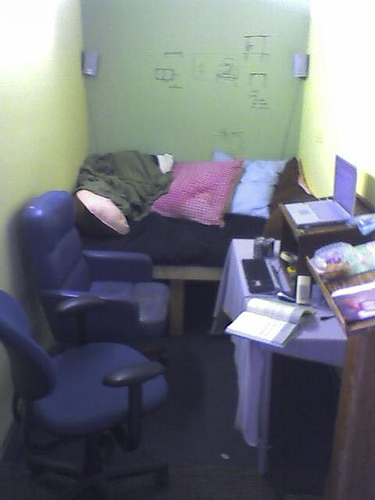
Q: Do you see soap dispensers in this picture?
A: No, there are no soap dispensers.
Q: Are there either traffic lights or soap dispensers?
A: No, there are no soap dispensers or traffic lights.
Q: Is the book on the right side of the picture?
A: Yes, the book is on the right of the image.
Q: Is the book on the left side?
A: No, the book is on the right of the image.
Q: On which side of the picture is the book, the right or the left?
A: The book is on the right of the image.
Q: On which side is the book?
A: The book is on the right of the image.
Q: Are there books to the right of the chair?
A: Yes, there is a book to the right of the chair.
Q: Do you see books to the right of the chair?
A: Yes, there is a book to the right of the chair.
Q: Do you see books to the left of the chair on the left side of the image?
A: No, the book is to the right of the chair.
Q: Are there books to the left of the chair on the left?
A: No, the book is to the right of the chair.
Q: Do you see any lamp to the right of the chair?
A: No, there is a book to the right of the chair.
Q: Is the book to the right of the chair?
A: Yes, the book is to the right of the chair.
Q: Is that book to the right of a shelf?
A: No, the book is to the right of the chair.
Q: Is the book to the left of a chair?
A: No, the book is to the right of a chair.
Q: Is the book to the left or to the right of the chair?
A: The book is to the right of the chair.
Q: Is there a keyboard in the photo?
A: Yes, there is a keyboard.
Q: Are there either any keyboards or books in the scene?
A: Yes, there is a keyboard.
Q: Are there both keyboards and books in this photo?
A: Yes, there are both a keyboard and a book.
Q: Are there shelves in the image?
A: No, there are no shelves.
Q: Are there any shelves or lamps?
A: No, there are no shelves or lamps.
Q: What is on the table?
A: The keyboard is on the table.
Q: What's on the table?
A: The keyboard is on the table.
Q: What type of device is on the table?
A: The device is a keyboard.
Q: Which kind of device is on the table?
A: The device is a keyboard.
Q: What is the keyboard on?
A: The keyboard is on the table.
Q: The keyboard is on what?
A: The keyboard is on the table.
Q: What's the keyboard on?
A: The keyboard is on the table.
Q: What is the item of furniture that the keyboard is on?
A: The piece of furniture is a table.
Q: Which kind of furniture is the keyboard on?
A: The keyboard is on the table.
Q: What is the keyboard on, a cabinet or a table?
A: The keyboard is on a table.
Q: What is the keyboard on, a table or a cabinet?
A: The keyboard is on a table.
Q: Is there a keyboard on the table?
A: Yes, there is a keyboard on the table.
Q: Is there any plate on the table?
A: No, there is a keyboard on the table.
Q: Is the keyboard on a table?
A: Yes, the keyboard is on a table.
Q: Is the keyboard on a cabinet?
A: No, the keyboard is on a table.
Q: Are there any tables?
A: Yes, there is a table.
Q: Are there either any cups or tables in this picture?
A: Yes, there is a table.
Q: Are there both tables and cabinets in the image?
A: No, there is a table but no cabinets.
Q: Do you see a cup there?
A: No, there are no cups.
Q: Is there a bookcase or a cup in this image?
A: No, there are no cups or bookcases.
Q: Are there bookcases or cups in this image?
A: No, there are no cups or bookcases.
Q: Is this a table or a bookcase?
A: This is a table.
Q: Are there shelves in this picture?
A: No, there are no shelves.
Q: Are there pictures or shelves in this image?
A: No, there are no shelves or pictures.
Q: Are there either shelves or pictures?
A: No, there are no shelves or pictures.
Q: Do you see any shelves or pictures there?
A: No, there are no shelves or pictures.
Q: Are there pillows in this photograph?
A: Yes, there is a pillow.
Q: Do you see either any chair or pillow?
A: Yes, there is a pillow.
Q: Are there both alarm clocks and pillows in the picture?
A: No, there is a pillow but no alarm clocks.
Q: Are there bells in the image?
A: No, there are no bells.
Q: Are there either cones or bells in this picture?
A: No, there are no bells or cones.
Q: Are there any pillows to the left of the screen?
A: Yes, there is a pillow to the left of the screen.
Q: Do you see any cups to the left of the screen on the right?
A: No, there is a pillow to the left of the screen.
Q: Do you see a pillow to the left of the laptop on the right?
A: Yes, there is a pillow to the left of the laptop.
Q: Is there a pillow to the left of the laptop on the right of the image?
A: Yes, there is a pillow to the left of the laptop.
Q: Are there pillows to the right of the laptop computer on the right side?
A: No, the pillow is to the left of the laptop.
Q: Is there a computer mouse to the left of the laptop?
A: No, there is a pillow to the left of the laptop.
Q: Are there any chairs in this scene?
A: Yes, there is a chair.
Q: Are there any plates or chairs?
A: Yes, there is a chair.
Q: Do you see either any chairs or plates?
A: Yes, there is a chair.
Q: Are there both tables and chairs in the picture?
A: Yes, there are both a chair and a table.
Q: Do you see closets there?
A: No, there are no closets.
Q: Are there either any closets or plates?
A: No, there are no closets or plates.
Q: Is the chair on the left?
A: Yes, the chair is on the left of the image.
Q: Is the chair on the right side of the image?
A: No, the chair is on the left of the image.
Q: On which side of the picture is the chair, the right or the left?
A: The chair is on the left of the image.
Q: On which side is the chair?
A: The chair is on the left of the image.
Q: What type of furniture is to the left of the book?
A: The piece of furniture is a chair.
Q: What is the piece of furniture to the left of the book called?
A: The piece of furniture is a chair.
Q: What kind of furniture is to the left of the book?
A: The piece of furniture is a chair.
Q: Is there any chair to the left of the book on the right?
A: Yes, there is a chair to the left of the book.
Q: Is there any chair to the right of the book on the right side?
A: No, the chair is to the left of the book.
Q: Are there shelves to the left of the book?
A: No, there is a chair to the left of the book.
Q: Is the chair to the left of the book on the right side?
A: Yes, the chair is to the left of the book.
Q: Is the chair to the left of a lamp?
A: No, the chair is to the left of the book.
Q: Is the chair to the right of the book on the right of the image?
A: No, the chair is to the left of the book.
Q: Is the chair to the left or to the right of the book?
A: The chair is to the left of the book.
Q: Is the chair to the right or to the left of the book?
A: The chair is to the left of the book.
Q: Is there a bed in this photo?
A: Yes, there is a bed.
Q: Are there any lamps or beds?
A: Yes, there is a bed.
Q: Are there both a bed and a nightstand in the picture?
A: No, there is a bed but no nightstands.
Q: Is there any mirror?
A: No, there are no mirrors.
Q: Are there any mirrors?
A: No, there are no mirrors.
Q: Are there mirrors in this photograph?
A: No, there are no mirrors.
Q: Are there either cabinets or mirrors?
A: No, there are no mirrors or cabinets.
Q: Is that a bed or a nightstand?
A: That is a bed.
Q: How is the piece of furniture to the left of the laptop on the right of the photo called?
A: The piece of furniture is a bed.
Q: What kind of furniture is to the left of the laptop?
A: The piece of furniture is a bed.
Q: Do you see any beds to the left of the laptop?
A: Yes, there is a bed to the left of the laptop.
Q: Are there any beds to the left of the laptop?
A: Yes, there is a bed to the left of the laptop.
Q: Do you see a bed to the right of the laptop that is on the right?
A: No, the bed is to the left of the laptop.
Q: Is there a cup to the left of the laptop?
A: No, there is a bed to the left of the laptop.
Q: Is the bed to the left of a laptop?
A: Yes, the bed is to the left of a laptop.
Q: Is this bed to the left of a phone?
A: No, the bed is to the left of a laptop.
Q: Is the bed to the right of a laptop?
A: No, the bed is to the left of a laptop.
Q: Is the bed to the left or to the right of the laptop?
A: The bed is to the left of the laptop.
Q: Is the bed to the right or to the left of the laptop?
A: The bed is to the left of the laptop.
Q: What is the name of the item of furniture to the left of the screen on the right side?
A: The piece of furniture is a bed.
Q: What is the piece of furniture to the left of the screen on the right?
A: The piece of furniture is a bed.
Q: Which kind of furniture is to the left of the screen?
A: The piece of furniture is a bed.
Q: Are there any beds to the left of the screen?
A: Yes, there is a bed to the left of the screen.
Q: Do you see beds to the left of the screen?
A: Yes, there is a bed to the left of the screen.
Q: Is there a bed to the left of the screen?
A: Yes, there is a bed to the left of the screen.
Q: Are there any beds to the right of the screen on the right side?
A: No, the bed is to the left of the screen.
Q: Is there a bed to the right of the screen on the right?
A: No, the bed is to the left of the screen.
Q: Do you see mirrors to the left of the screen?
A: No, there is a bed to the left of the screen.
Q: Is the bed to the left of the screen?
A: Yes, the bed is to the left of the screen.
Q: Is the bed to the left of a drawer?
A: No, the bed is to the left of the screen.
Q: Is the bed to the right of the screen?
A: No, the bed is to the left of the screen.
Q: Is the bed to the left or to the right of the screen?
A: The bed is to the left of the screen.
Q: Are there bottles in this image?
A: No, there are no bottles.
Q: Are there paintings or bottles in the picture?
A: No, there are no bottles or paintings.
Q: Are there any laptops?
A: Yes, there is a laptop.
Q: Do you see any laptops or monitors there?
A: Yes, there is a laptop.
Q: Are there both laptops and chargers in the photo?
A: No, there is a laptop but no chargers.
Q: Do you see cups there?
A: No, there are no cups.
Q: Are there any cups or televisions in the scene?
A: No, there are no cups or televisions.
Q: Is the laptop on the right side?
A: Yes, the laptop is on the right of the image.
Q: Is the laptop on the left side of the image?
A: No, the laptop is on the right of the image.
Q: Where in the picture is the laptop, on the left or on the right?
A: The laptop is on the right of the image.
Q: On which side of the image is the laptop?
A: The laptop is on the right of the image.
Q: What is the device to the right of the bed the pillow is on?
A: The device is a laptop.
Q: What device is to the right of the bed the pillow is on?
A: The device is a laptop.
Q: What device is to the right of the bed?
A: The device is a laptop.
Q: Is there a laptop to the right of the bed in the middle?
A: Yes, there is a laptop to the right of the bed.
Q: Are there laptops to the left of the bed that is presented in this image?
A: No, the laptop is to the right of the bed.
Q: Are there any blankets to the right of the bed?
A: No, there is a laptop to the right of the bed.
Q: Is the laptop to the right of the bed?
A: Yes, the laptop is to the right of the bed.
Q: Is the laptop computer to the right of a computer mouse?
A: No, the laptop computer is to the right of the bed.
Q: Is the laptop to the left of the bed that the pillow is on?
A: No, the laptop is to the right of the bed.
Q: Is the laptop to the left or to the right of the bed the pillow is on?
A: The laptop is to the right of the bed.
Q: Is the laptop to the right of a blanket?
A: No, the laptop is to the right of the pillow.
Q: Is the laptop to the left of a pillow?
A: No, the laptop is to the right of a pillow.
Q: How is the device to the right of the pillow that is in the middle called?
A: The device is a laptop.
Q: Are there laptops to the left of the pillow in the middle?
A: No, the laptop is to the right of the pillow.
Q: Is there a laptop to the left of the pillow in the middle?
A: No, the laptop is to the right of the pillow.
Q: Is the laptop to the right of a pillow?
A: Yes, the laptop is to the right of a pillow.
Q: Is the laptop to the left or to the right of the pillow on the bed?
A: The laptop is to the right of the pillow.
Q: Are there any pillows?
A: Yes, there is a pillow.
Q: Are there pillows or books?
A: Yes, there is a pillow.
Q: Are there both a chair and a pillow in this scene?
A: Yes, there are both a pillow and a chair.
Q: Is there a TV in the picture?
A: No, there are no televisions.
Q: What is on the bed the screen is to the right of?
A: The pillow is on the bed.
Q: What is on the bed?
A: The pillow is on the bed.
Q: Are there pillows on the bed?
A: Yes, there is a pillow on the bed.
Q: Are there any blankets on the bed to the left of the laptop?
A: No, there is a pillow on the bed.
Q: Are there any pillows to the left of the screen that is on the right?
A: Yes, there is a pillow to the left of the screen.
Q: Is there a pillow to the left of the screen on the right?
A: Yes, there is a pillow to the left of the screen.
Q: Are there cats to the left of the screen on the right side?
A: No, there is a pillow to the left of the screen.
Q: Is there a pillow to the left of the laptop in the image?
A: Yes, there is a pillow to the left of the laptop.